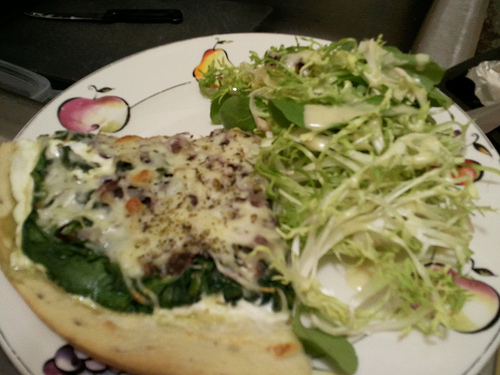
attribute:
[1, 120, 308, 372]
pizza — slice of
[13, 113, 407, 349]
pizza — slice of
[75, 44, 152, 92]
plate — white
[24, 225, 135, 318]
spinach — green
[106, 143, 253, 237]
cheese — melted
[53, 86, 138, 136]
apple design — reddish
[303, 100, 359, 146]
sauce — on pizza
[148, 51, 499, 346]
vegetable — on pizza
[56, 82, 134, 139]
apple — image of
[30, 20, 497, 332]
plate — with pizza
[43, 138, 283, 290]
cheese — on pizza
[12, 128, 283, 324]
pizza — vegetarian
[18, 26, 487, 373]
salad — spinach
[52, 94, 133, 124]
apple — painted red and green 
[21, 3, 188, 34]
knife — dark handled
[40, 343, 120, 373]
grapes — purple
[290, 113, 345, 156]
dressing — creamy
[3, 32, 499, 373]
plate — with food, white, holding pizza, round,  round 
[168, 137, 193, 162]
meat — brown chunks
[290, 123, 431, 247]
salad — wild, green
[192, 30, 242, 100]
pear — yellow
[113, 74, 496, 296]
plate — round